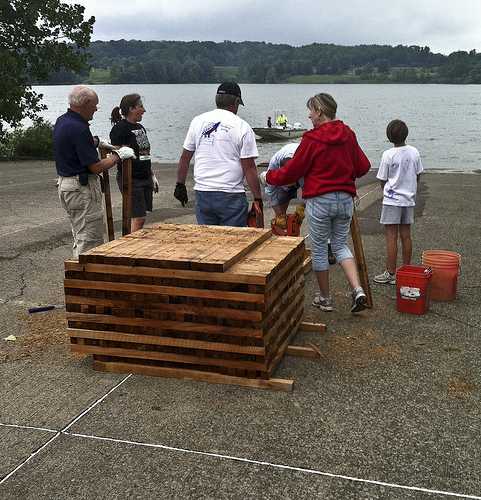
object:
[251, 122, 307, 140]
boat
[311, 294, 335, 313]
shoes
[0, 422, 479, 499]
line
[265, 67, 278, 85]
trees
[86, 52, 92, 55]
leaves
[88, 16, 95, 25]
leaves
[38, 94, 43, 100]
leaves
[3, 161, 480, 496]
road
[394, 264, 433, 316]
box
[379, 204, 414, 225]
shorts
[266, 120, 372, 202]
jacket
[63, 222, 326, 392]
wood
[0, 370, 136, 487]
lines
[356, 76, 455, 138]
water